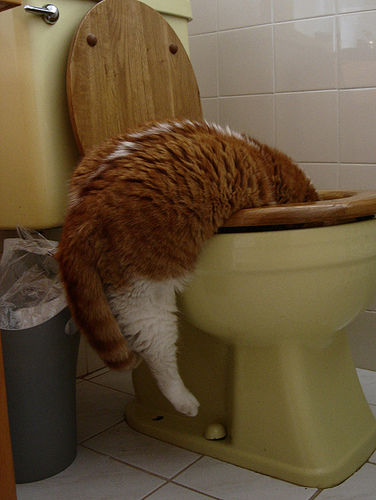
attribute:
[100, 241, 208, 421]
leg — white, hanging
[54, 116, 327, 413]
cat — drinking, orange, thirsty, brown, white, inside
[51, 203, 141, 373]
tail — striped, brown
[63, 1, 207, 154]
lid — wooden, open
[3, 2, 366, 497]
toilet — yellow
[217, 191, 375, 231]
seat — wooden, brown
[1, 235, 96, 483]
trash can — gray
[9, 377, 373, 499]
floor — tile, white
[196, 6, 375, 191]
wall — tile, white, tiled, off-white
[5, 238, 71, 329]
bag — plastic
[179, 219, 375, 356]
bowl — yellow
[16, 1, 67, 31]
handle — silver, metal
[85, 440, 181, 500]
tiles — white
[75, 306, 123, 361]
stripes — orange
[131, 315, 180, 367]
fur — ruffled, white